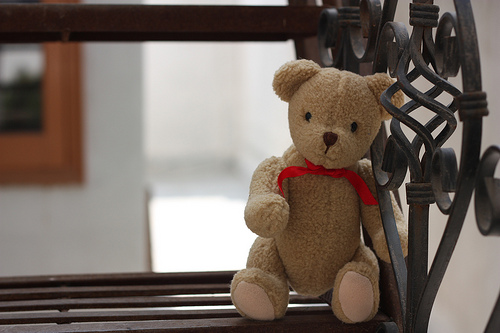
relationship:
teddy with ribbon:
[265, 62, 400, 312] [278, 159, 380, 217]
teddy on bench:
[265, 62, 400, 312] [5, 271, 377, 332]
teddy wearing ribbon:
[265, 62, 400, 312] [278, 159, 380, 217]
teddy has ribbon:
[265, 62, 400, 312] [278, 159, 380, 217]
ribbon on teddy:
[278, 159, 380, 217] [265, 62, 400, 312]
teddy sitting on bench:
[265, 62, 400, 312] [5, 271, 377, 332]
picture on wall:
[3, 43, 86, 187] [106, 60, 141, 117]